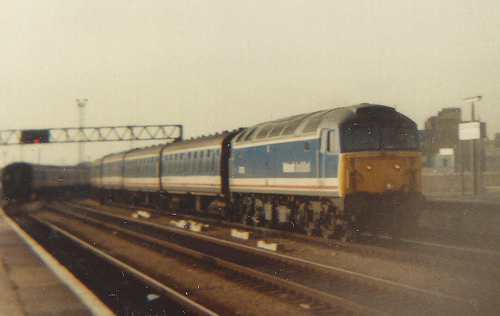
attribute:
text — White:
[281, 161, 309, 173]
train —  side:
[220, 104, 460, 249]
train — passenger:
[101, 84, 385, 243]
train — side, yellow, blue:
[85, 102, 426, 242]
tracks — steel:
[187, 213, 392, 310]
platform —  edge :
[1, 211, 72, 308]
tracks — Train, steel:
[102, 189, 367, 314]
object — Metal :
[4, 119, 182, 141]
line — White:
[44, 255, 68, 287]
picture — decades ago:
[6, 8, 484, 302]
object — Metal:
[4, 120, 180, 148]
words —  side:
[274, 157, 316, 172]